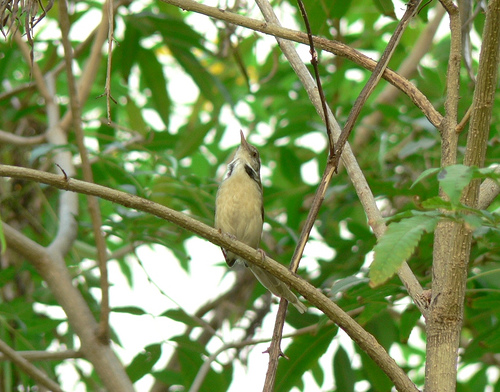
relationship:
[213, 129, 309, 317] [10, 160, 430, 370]
bird sitting on branch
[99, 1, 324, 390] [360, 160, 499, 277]
sky seen through leaves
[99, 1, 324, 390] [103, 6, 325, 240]
sky seen through leaves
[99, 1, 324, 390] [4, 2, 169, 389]
sky seen through branches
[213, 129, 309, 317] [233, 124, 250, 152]
bird has a beak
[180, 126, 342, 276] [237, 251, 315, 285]
bird has a foot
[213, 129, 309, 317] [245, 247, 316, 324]
bird has a tail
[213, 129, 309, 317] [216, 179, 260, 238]
bird has chest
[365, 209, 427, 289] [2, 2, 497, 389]
leaf on tree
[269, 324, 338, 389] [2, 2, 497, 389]
leaf on tree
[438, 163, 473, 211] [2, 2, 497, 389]
leaf on tree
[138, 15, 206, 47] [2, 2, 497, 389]
leaf on tree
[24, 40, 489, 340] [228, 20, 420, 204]
tree has branches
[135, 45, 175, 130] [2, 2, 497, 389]
leaf on tree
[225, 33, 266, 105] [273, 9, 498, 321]
leaf on tree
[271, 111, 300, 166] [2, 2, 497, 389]
leaf on tree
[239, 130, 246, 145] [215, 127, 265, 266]
beak on bird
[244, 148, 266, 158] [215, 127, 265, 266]
eye on bird